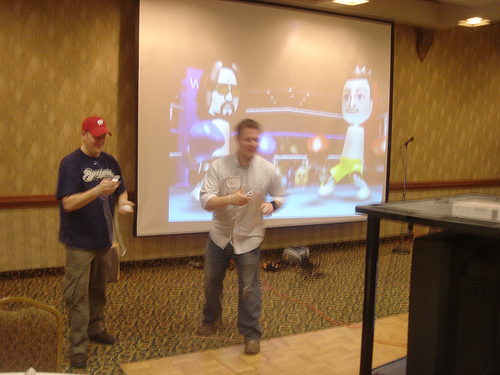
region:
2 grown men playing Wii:
[37, 103, 322, 354]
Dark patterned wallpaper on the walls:
[5, 4, 134, 154]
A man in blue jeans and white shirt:
[191, 98, 288, 358]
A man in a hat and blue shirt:
[44, 98, 150, 373]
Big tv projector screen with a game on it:
[139, 0, 387, 210]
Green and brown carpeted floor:
[15, 258, 417, 324]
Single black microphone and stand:
[380, 113, 420, 255]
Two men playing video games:
[48, 96, 278, 371]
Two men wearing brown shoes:
[45, 110, 298, 374]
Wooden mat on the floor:
[139, 313, 419, 373]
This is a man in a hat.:
[37, 99, 134, 372]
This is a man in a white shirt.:
[193, 100, 298, 373]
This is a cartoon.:
[320, 73, 378, 207]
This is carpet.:
[296, 272, 372, 322]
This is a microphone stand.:
[384, 127, 429, 246]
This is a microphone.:
[393, 132, 422, 156]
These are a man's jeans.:
[174, 227, 272, 366]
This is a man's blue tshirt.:
[35, 150, 139, 260]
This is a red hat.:
[77, 109, 115, 136]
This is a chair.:
[2, 281, 78, 368]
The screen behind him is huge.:
[156, 17, 387, 214]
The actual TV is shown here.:
[375, 220, 499, 370]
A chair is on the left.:
[2, 285, 69, 369]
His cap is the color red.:
[63, 105, 125, 161]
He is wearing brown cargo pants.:
[53, 228, 125, 364]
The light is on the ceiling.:
[407, 6, 499, 31]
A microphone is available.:
[395, 123, 417, 255]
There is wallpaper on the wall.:
[13, 18, 118, 105]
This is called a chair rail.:
[1, 171, 60, 238]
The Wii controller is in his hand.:
[223, 183, 254, 215]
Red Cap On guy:
[67, 111, 123, 143]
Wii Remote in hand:
[114, 200, 146, 265]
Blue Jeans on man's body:
[190, 228, 276, 349]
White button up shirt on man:
[206, 143, 301, 248]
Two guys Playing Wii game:
[32, 99, 307, 372]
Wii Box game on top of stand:
[449, 190, 497, 251]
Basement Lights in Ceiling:
[424, 0, 499, 38]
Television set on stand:
[394, 217, 496, 364]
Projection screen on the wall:
[142, 3, 405, 229]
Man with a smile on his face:
[228, 105, 278, 262]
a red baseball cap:
[78, 113, 116, 138]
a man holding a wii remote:
[201, 107, 284, 350]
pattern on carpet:
[124, 284, 181, 345]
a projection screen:
[140, 0, 397, 140]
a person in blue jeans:
[194, 223, 274, 355]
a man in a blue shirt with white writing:
[53, 135, 138, 246]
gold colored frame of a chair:
[1, 292, 81, 373]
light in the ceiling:
[454, 1, 489, 37]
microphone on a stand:
[397, 130, 429, 188]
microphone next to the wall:
[393, 130, 431, 191]